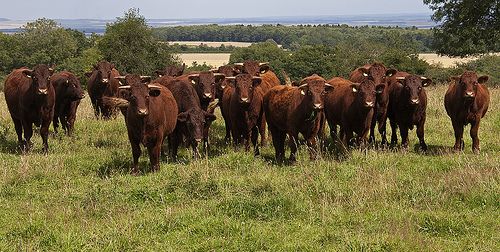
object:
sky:
[0, 0, 497, 38]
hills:
[147, 23, 443, 53]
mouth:
[310, 107, 324, 111]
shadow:
[413, 143, 459, 158]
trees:
[355, 25, 359, 28]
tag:
[301, 89, 306, 95]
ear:
[301, 86, 309, 94]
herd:
[4, 60, 491, 177]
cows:
[86, 60, 121, 121]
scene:
[0, 0, 500, 252]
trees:
[218, 43, 226, 50]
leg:
[126, 126, 144, 177]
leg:
[146, 124, 164, 172]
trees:
[272, 27, 290, 44]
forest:
[148, 22, 500, 53]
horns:
[114, 76, 125, 79]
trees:
[2, 15, 79, 76]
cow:
[118, 82, 179, 177]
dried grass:
[168, 52, 231, 70]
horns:
[395, 76, 405, 79]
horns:
[421, 76, 427, 79]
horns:
[139, 76, 151, 80]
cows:
[49, 70, 86, 138]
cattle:
[221, 73, 265, 158]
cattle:
[261, 79, 335, 167]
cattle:
[324, 76, 387, 155]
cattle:
[387, 74, 434, 156]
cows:
[3, 63, 57, 157]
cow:
[444, 70, 491, 155]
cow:
[349, 61, 397, 148]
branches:
[470, 3, 497, 21]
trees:
[421, 0, 500, 60]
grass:
[0, 84, 500, 252]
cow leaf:
[262, 79, 334, 167]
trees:
[228, 41, 291, 86]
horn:
[148, 85, 163, 89]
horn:
[118, 85, 131, 88]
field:
[0, 40, 500, 70]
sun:
[0, 82, 500, 251]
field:
[0, 79, 500, 250]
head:
[118, 82, 163, 116]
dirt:
[157, 41, 261, 48]